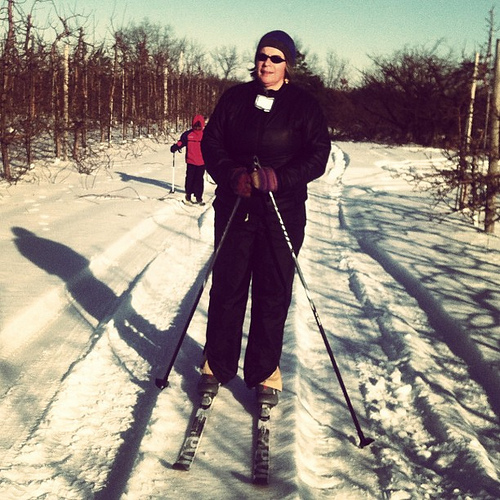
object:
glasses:
[256, 52, 285, 66]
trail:
[0, 139, 498, 498]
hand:
[170, 144, 179, 152]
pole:
[170, 146, 176, 194]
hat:
[258, 31, 297, 60]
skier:
[168, 109, 217, 204]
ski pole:
[260, 181, 376, 457]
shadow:
[5, 219, 202, 392]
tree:
[457, 43, 481, 214]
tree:
[480, 35, 499, 232]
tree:
[52, 16, 73, 160]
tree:
[163, 43, 170, 137]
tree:
[192, 42, 207, 121]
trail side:
[329, 57, 498, 226]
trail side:
[0, 1, 250, 185]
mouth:
[258, 67, 274, 77]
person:
[199, 29, 331, 401]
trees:
[335, 38, 487, 145]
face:
[258, 48, 288, 87]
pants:
[201, 187, 306, 382]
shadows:
[324, 193, 485, 439]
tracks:
[317, 141, 500, 500]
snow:
[0, 104, 500, 500]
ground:
[0, 124, 497, 500]